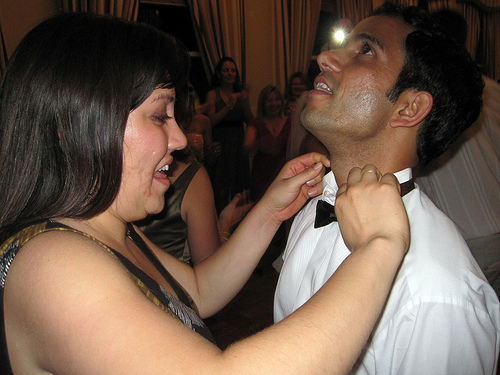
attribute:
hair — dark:
[1, 11, 186, 242]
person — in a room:
[261, 7, 495, 373]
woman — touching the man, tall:
[0, 9, 410, 372]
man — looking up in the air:
[265, 2, 496, 372]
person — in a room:
[243, 82, 291, 158]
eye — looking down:
[350, 34, 390, 66]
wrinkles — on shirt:
[430, 281, 497, 352]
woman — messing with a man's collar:
[15, 7, 269, 359]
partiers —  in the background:
[179, 42, 320, 240]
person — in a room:
[242, 12, 492, 374]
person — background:
[205, 53, 250, 209]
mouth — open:
[154, 156, 178, 188]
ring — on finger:
[353, 162, 390, 197]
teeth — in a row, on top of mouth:
[153, 159, 171, 174]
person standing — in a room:
[202, 54, 254, 204]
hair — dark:
[366, 6, 484, 163]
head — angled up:
[281, 4, 491, 194]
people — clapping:
[220, 50, 290, 123]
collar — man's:
[324, 176, 427, 199]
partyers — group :
[195, 45, 292, 143]